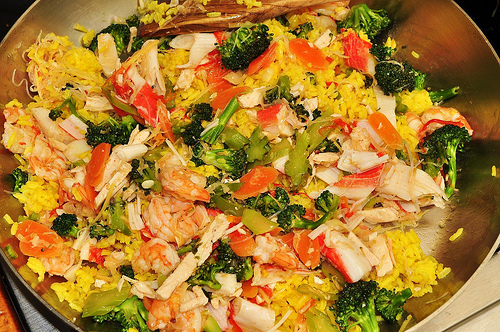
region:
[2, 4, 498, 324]
Meal in a bowl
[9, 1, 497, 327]
Meal has broccoli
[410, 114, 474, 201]
Piece of broccoli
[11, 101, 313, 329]
Dish has shrimps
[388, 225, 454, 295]
Rice is yellow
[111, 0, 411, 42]
Spoon in the dish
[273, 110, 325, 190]
Stem of broccoli is green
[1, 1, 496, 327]
Bowl with food is color silver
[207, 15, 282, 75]
Piece of broccoli next to spoon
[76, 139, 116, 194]
Carrot is cooked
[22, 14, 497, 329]
the plate of food is quite colorful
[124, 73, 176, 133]
it appears to have crab in it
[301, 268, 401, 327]
i see broccoli in it, too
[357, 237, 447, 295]
yellow rice is part of the dinner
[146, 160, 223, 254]
shrimp are part of the mixture too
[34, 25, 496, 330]
the meal looks very tasty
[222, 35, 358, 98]
there may be some red peppers in it as well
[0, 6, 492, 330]
the bowl is quite large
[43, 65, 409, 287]
this would make a really yummy dinner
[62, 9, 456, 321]
i would love to have this for my dinner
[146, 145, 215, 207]
shrimp is orange and pink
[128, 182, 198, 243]
shrimp is orange and pink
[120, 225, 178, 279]
shrimp is orange and pink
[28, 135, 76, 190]
shrimp is orange and pink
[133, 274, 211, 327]
shrimp is orange and pink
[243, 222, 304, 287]
shrimp is orange and pink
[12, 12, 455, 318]
tasty seafood and vegetable plate.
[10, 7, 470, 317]
delicious seafood and vegetable plate.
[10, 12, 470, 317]
fantastic seafood and vegetable plate.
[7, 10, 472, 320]
delightful seafood and vegetable plate.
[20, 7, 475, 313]
nice seafood and vegetable mix.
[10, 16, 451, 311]
great seafood and vegetable mix.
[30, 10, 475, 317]
delicious seafood and vegetable mix.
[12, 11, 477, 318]
special seafood and vegetable mix.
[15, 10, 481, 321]
flavorful seafood and vegetable mix.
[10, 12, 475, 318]
attractive seafood and vegetable mix.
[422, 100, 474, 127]
a piece of shrimp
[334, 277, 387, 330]
a piece of broccoli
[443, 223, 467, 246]
one grain of yellow rice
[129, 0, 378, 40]
a wooden spoon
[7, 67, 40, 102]
possibly a noodle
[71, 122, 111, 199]
a slice of a carrot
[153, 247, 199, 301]
a chunk of food that is either tofu or chicken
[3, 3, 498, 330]
a bowl of food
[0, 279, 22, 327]
some of the wooden table the bowl is sitting on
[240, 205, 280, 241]
a slice of bell pepper